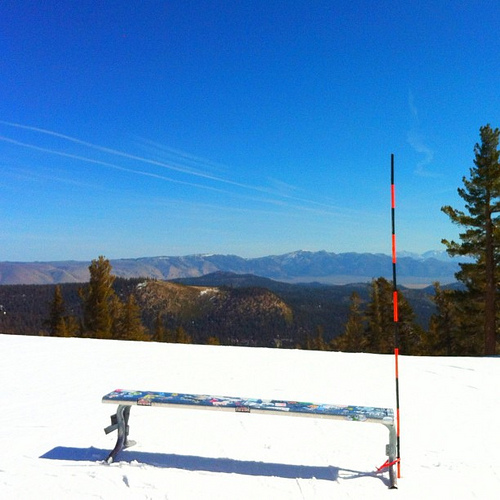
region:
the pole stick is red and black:
[361, 130, 432, 480]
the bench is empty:
[56, 360, 408, 470]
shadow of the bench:
[30, 410, 335, 490]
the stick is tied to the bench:
[350, 450, 405, 472]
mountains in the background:
[35, 236, 325, 271]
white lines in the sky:
[25, 85, 331, 225]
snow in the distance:
[160, 260, 226, 310]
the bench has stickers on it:
[105, 360, 390, 426]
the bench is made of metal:
[72, 341, 409, 484]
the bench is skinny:
[94, 331, 406, 433]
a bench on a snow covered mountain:
[98, 358, 412, 480]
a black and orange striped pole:
[370, 155, 421, 482]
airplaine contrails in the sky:
[10, 104, 355, 248]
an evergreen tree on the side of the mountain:
[432, 114, 499, 246]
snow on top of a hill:
[14, 340, 336, 391]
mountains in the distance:
[6, 236, 493, 306]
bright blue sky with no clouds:
[50, 8, 390, 80]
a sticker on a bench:
[129, 395, 160, 409]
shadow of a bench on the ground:
[39, 425, 404, 491]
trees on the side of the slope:
[171, 290, 363, 343]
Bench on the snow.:
[98, 385, 413, 491]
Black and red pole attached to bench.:
[387, 143, 405, 479]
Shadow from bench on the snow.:
[38, 443, 343, 484]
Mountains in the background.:
[0, 230, 460, 295]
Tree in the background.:
[445, 119, 496, 356]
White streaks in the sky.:
[26, 119, 359, 216]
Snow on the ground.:
[5, 333, 493, 498]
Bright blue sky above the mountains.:
[2, 4, 497, 111]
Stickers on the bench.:
[114, 388, 394, 425]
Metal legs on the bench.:
[105, 405, 142, 465]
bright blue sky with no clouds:
[160, 24, 387, 110]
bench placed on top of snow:
[85, 377, 422, 464]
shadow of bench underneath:
[40, 449, 406, 484]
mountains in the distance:
[165, 229, 392, 299]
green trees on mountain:
[151, 255, 487, 335]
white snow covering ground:
[25, 350, 82, 385]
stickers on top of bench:
[102, 389, 380, 424]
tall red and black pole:
[385, 150, 418, 481]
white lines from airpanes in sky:
[35, 136, 242, 194]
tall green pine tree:
[440, 128, 499, 354]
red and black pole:
[371, 141, 413, 488]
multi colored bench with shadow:
[35, 376, 412, 498]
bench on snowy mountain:
[88, 321, 408, 496]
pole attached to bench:
[92, 122, 424, 492]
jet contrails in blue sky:
[0, 73, 474, 233]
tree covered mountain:
[127, 267, 327, 346]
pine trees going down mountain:
[288, 131, 497, 357]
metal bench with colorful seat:
[95, 383, 415, 493]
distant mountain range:
[11, 231, 498, 311]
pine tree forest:
[26, 243, 498, 348]